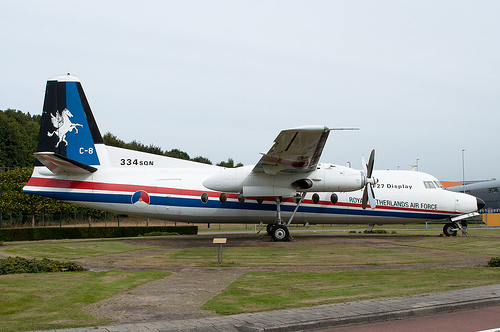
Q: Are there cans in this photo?
A: No, there are no cans.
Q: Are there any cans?
A: No, there are no cans.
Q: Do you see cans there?
A: No, there are no cans.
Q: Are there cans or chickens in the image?
A: No, there are no cans or chickens.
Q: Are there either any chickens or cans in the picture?
A: No, there are no cans or chickens.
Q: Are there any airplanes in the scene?
A: Yes, there is an airplane.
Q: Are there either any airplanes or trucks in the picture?
A: Yes, there is an airplane.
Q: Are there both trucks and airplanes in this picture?
A: No, there is an airplane but no trucks.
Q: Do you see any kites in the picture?
A: No, there are no kites.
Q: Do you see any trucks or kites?
A: No, there are no kites or trucks.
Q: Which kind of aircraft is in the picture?
A: The aircraft is an airplane.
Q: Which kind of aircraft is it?
A: The aircraft is an airplane.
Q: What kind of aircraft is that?
A: This is an airplane.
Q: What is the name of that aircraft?
A: This is an airplane.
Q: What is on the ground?
A: The plane is on the ground.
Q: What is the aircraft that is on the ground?
A: The aircraft is an airplane.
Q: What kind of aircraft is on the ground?
A: The aircraft is an airplane.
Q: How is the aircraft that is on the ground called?
A: The aircraft is an airplane.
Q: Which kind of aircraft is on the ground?
A: The aircraft is an airplane.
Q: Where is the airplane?
A: The airplane is on the ground.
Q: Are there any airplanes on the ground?
A: Yes, there is an airplane on the ground.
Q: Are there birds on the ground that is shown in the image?
A: No, there is an airplane on the ground.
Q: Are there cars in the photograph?
A: No, there are no cars.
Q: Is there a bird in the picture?
A: No, there are no birds.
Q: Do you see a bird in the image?
A: No, there are no birds.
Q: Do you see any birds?
A: No, there are no birds.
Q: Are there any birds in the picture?
A: No, there are no birds.